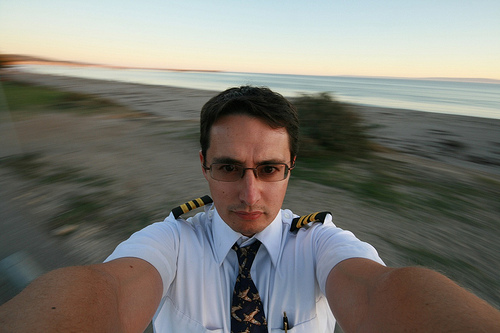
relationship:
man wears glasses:
[0, 86, 500, 332] [202, 160, 295, 182]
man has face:
[0, 86, 500, 332] [204, 112, 292, 235]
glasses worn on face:
[202, 160, 295, 182] [204, 112, 292, 235]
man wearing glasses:
[0, 86, 500, 332] [202, 160, 295, 182]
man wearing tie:
[0, 86, 500, 332] [232, 239, 269, 332]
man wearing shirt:
[0, 86, 500, 332] [102, 194, 387, 333]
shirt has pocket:
[102, 194, 387, 333] [270, 314, 319, 332]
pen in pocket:
[282, 311, 290, 332] [270, 314, 319, 332]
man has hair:
[0, 86, 500, 332] [200, 86, 301, 173]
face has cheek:
[204, 112, 292, 235] [207, 178, 241, 205]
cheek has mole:
[207, 178, 241, 205] [220, 190, 225, 194]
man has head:
[0, 86, 500, 332] [197, 84, 302, 236]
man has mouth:
[0, 86, 500, 332] [230, 208, 269, 220]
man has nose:
[0, 86, 500, 332] [237, 168, 263, 207]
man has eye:
[0, 86, 500, 332] [219, 164, 239, 174]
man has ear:
[0, 86, 500, 332] [291, 152, 297, 169]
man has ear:
[0, 86, 500, 332] [198, 149, 206, 176]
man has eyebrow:
[0, 86, 500, 332] [213, 155, 246, 165]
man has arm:
[0, 86, 500, 332] [314, 222, 499, 333]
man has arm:
[0, 86, 500, 332] [0, 220, 179, 333]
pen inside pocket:
[282, 311, 290, 332] [270, 314, 319, 332]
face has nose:
[204, 112, 292, 235] [237, 168, 263, 207]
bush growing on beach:
[289, 92, 387, 166] [0, 70, 500, 333]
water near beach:
[15, 63, 499, 119] [0, 70, 500, 333]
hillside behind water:
[0, 54, 74, 63] [15, 63, 499, 119]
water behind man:
[15, 63, 499, 119] [0, 86, 500, 332]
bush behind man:
[289, 92, 387, 166] [0, 86, 500, 332]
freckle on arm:
[51, 304, 56, 310] [0, 220, 179, 333]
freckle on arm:
[128, 263, 133, 269] [0, 220, 179, 333]